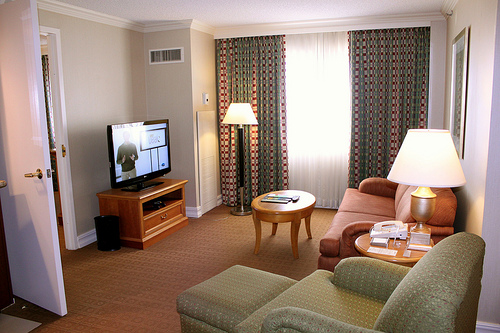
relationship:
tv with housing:
[102, 117, 171, 192] [104, 118, 173, 189]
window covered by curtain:
[212, 8, 447, 217] [215, 26, 430, 208]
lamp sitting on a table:
[387, 127, 453, 244] [353, 220, 440, 260]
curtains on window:
[344, 26, 446, 228] [220, 29, 445, 201]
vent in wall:
[146, 47, 183, 63] [140, 30, 192, 211]